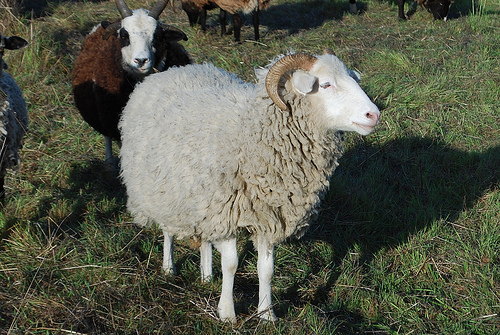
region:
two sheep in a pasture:
[62, 6, 382, 333]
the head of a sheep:
[264, 43, 391, 158]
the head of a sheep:
[103, 8, 161, 75]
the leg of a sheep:
[255, 225, 284, 325]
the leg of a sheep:
[211, 235, 245, 325]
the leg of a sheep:
[153, 227, 178, 277]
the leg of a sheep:
[191, 230, 220, 282]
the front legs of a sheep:
[209, 232, 282, 329]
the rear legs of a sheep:
[153, 223, 220, 290]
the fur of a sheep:
[151, 93, 268, 218]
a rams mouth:
[354, 120, 377, 135]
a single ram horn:
[263, 50, 315, 110]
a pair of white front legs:
[216, 233, 285, 323]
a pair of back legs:
[156, 218, 215, 285]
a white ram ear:
[292, 69, 317, 94]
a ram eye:
[318, 80, 335, 90]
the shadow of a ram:
[291, 130, 499, 303]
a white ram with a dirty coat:
[120, 55, 382, 329]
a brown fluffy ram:
[72, 1, 181, 161]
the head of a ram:
[265, 52, 382, 135]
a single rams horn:
[261, 50, 316, 110]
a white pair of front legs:
[213, 236, 278, 325]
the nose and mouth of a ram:
[351, 109, 381, 133]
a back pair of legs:
[150, 209, 217, 284]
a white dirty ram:
[115, 44, 380, 324]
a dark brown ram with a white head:
[66, 0, 184, 163]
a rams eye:
[320, 81, 331, 90]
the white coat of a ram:
[123, 73, 314, 241]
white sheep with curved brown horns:
[120, 52, 379, 326]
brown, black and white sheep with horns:
[73, 0, 194, 172]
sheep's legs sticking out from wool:
[161, 229, 277, 325]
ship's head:
[260, 48, 381, 137]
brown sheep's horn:
[266, 52, 317, 110]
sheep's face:
[292, 54, 379, 134]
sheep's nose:
[354, 102, 379, 135]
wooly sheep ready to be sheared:
[117, 54, 383, 324]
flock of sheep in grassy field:
[0, 0, 498, 333]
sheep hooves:
[214, 301, 280, 322]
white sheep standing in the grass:
[115, 53, 397, 333]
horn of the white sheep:
[262, 48, 318, 103]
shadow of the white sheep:
[309, 115, 499, 297]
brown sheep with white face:
[62, 15, 197, 183]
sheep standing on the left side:
[0, 33, 34, 228]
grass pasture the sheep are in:
[8, 8, 478, 325]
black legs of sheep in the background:
[180, 0, 475, 42]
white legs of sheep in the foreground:
[161, 233, 279, 319]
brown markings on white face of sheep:
[120, 28, 160, 46]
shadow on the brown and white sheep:
[64, 78, 129, 143]